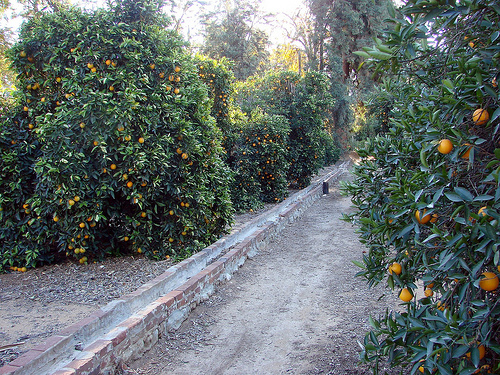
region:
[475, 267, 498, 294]
Orange is orange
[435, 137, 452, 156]
Orange next to green leaf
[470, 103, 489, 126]
Orange by brown branch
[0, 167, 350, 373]
Brick slab next to dirt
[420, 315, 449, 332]
Leaf is small and green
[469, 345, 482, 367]
Leaf covering orange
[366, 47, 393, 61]
Leaf is small and green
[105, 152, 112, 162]
Leaf is small and green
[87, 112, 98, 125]
Leaf is small and green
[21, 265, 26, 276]
Orange on dirt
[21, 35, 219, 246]
large bushes filled with lemons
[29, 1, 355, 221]
numerous lemon trees along a path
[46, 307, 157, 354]
a red brick path divider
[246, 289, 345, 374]
gray dirt on a pathway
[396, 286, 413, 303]
a perfectly round yellow lemon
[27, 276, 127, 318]
brown leaves on the ground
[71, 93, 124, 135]
patches of green leaves on a lemon tree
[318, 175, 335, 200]
a small brown structure along a path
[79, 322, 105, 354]
a crevice between two sections of brick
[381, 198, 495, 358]
a close up of yellow lemons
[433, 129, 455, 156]
orange on a tree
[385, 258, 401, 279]
orange on a tree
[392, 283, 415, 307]
orange on a tree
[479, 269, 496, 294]
orange on a tree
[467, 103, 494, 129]
orange on a tree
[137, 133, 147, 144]
orange on a tree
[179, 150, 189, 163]
orange on a tree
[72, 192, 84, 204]
orange on a tree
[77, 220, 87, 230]
orange on a tree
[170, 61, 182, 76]
orange on a tree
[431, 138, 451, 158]
orange in fruit orchard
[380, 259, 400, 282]
orange in fruit orchard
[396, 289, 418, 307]
orange in fruit orchard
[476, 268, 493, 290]
orange in fruit orchard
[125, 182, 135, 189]
orange in fruit orchard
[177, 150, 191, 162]
orange in fruit orchard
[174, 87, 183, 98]
orange in fruit orchard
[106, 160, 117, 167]
orange in fruit orchard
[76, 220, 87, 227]
orange in fruit orchard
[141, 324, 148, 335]
edge of a wall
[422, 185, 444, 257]
part of a flower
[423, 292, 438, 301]
part of a fruit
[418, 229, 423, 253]
tip of a leaf